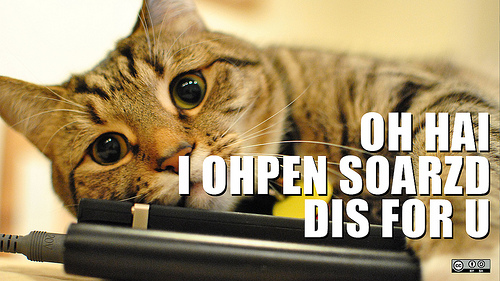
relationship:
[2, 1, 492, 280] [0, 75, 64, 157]
cat has ear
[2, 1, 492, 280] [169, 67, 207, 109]
cat has eye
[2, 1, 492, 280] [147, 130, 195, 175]
cat has nose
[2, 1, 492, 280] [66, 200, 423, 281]
cat on laptop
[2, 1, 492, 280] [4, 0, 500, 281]
cat has fur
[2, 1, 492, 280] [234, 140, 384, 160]
cat has whisker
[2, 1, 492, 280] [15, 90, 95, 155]
cat has lashes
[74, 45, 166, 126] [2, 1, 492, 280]
pattern on cat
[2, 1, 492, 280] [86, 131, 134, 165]
cat has eye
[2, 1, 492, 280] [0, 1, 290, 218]
cat has head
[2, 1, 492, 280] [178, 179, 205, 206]
cat has mouth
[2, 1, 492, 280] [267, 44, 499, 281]
cat has body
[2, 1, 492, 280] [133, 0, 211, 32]
cat has ear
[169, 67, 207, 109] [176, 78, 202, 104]
eye has pupil